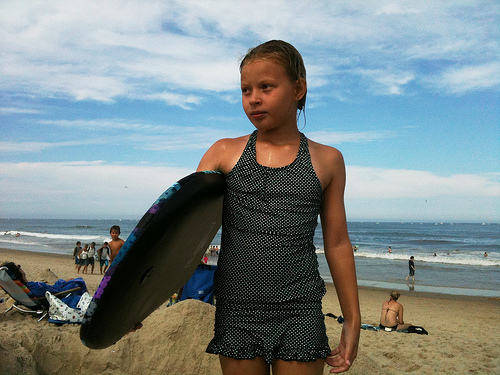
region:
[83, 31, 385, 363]
girl with a surfboard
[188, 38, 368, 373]
girl in black and white bathing suit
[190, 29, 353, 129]
girl with wet hair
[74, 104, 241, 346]
surfboard with black bottom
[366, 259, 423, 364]
person sitting on sandy beach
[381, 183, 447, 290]
person standing in water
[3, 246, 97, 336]
person sitting on a beach chair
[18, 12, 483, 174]
clouds in sky of photo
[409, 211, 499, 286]
people in waves of water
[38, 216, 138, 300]
group of people on beach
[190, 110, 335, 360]
Girl is wearing a black bathing suit with white dots.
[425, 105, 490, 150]
Part of the sky is blue.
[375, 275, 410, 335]
The back of a woman wearing a bikini.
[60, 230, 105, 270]
People standing on the beach.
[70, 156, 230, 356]
Girl is holding a boogie board.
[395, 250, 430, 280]
Person standing near the water.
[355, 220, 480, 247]
The water in the ocean is dark blue.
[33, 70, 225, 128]
Blue sky with wispy white clouds.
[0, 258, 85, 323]
A chair on the beach.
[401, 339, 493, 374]
The sand on the beach.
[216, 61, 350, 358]
A girl is visible.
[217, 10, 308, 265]
A girl is visible.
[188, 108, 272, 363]
A girl is visible.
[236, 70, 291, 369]
A girl is visible.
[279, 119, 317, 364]
A girl is visible.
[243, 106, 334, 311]
A girl is visible.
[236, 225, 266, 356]
A girl is visible.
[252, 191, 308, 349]
A girl is visible.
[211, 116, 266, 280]
A girl is visible.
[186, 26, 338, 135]
girl's hair is wet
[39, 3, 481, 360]
girl is holding surfboard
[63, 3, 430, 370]
girl is wearing swimsuit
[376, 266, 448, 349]
woman is sitting on towel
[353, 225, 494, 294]
people swimming in ocean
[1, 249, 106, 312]
woman is laying in chair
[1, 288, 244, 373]
sand is dug up behind girl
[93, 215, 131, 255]
boy's shirt is off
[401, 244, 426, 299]
man is standing in water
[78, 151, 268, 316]
bottom of surfboard is black